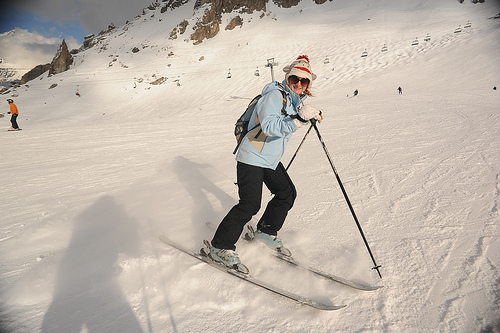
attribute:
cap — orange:
[6, 96, 14, 103]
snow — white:
[17, 141, 493, 329]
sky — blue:
[0, 0, 163, 51]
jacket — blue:
[236, 78, 298, 172]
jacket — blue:
[232, 78, 307, 172]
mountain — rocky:
[4, 7, 493, 328]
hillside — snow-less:
[82, 41, 227, 130]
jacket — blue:
[235, 76, 300, 168]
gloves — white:
[293, 100, 321, 125]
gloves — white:
[296, 92, 319, 121]